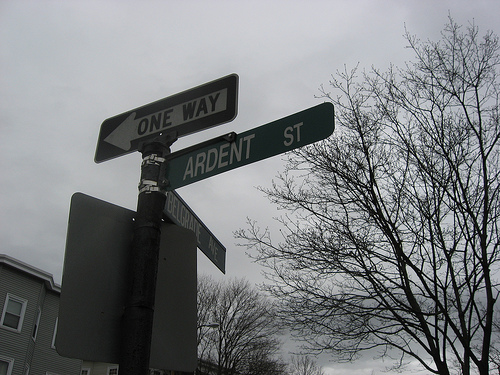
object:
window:
[0, 292, 30, 335]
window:
[31, 306, 42, 342]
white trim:
[31, 302, 43, 342]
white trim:
[0, 291, 29, 335]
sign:
[162, 102, 335, 193]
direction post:
[92, 71, 240, 165]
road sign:
[53, 189, 198, 375]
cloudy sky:
[0, 0, 500, 375]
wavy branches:
[232, 213, 363, 267]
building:
[0, 252, 240, 374]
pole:
[117, 142, 169, 374]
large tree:
[230, 8, 500, 375]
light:
[197, 323, 220, 332]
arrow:
[105, 87, 229, 152]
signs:
[163, 189, 226, 276]